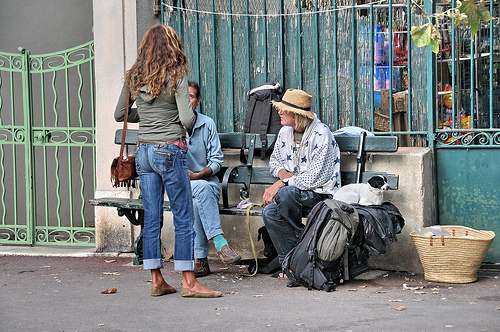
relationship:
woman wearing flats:
[112, 24, 224, 298] [180, 284, 223, 299]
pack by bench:
[278, 197, 346, 294] [86, 127, 400, 284]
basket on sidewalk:
[409, 223, 497, 284] [2, 254, 498, 329]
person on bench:
[258, 84, 345, 278] [86, 127, 400, 284]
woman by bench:
[112, 24, 224, 298] [86, 127, 400, 284]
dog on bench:
[331, 173, 392, 208] [86, 127, 400, 284]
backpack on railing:
[244, 83, 281, 158] [159, 0, 497, 148]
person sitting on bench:
[258, 84, 345, 278] [86, 127, 400, 284]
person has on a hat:
[258, 84, 345, 278] [268, 85, 321, 121]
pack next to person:
[278, 197, 346, 294] [258, 84, 345, 278]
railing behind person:
[159, 0, 497, 148] [258, 84, 345, 278]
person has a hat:
[258, 84, 345, 278] [268, 85, 321, 121]